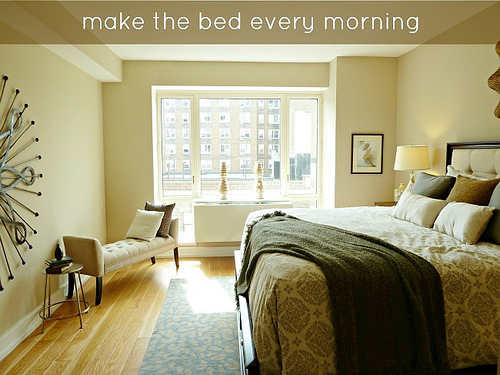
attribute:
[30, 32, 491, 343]
bedroom — large, expensive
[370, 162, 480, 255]
pillow — three, displayed, sit, throw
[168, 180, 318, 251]
bench — sitting, white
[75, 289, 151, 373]
floor — light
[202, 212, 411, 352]
spread — bed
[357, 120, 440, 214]
lamp — on, lit, white, small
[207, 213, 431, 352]
banket — hanging, draped, on top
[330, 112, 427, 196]
picture — hanging, art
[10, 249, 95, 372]
chair — standing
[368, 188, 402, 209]
table — standing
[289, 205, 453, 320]
comforter — covering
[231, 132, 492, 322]
bed — decorated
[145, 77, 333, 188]
view — hotel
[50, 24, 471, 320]
room — hotel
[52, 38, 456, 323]
hotel — five star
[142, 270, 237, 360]
rug — blue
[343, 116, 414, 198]
wall — piece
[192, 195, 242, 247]
unit — heat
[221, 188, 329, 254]
blanket — green